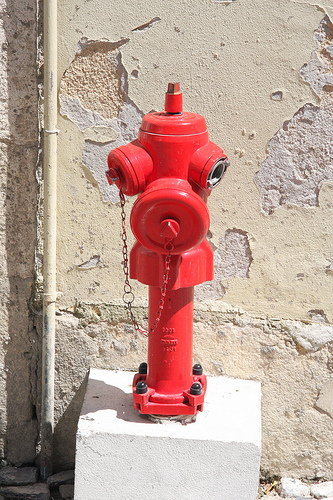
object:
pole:
[27, 8, 61, 184]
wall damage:
[267, 88, 283, 103]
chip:
[189, 226, 253, 304]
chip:
[305, 306, 332, 325]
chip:
[77, 251, 99, 272]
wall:
[56, 0, 332, 483]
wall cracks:
[253, 89, 321, 220]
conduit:
[42, 1, 58, 474]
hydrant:
[105, 74, 230, 426]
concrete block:
[71, 366, 264, 497]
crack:
[66, 27, 142, 136]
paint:
[254, 133, 301, 213]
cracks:
[238, 306, 320, 348]